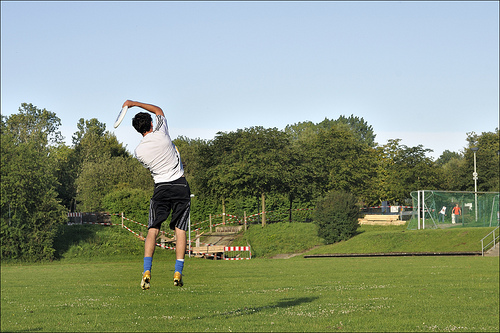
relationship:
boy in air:
[123, 78, 207, 264] [94, 87, 204, 151]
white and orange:
[214, 226, 241, 252] [222, 190, 258, 252]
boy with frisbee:
[122, 99, 195, 292] [105, 91, 139, 128]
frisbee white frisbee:
[114, 106, 129, 128] [105, 91, 139, 128]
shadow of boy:
[224, 280, 345, 325] [122, 99, 195, 292]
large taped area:
[255, 170, 401, 235] [334, 154, 460, 237]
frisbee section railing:
[114, 106, 129, 128] [207, 216, 265, 234]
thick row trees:
[218, 141, 270, 185] [22, 149, 124, 186]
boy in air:
[122, 99, 195, 292] [94, 87, 204, 151]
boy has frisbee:
[122, 99, 195, 292] [105, 91, 139, 128]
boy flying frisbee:
[122, 99, 195, 292] [105, 91, 139, 128]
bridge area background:
[213, 220, 245, 244] [198, 220, 235, 255]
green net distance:
[208, 106, 323, 171] [371, 167, 445, 223]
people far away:
[390, 188, 485, 247] [334, 154, 460, 237]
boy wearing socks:
[122, 99, 195, 292] [137, 259, 184, 275]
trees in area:
[22, 149, 124, 186] [334, 154, 460, 237]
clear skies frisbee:
[172, 28, 249, 61] [105, 91, 139, 128]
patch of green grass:
[280, 287, 348, 306] [251, 254, 359, 287]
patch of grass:
[280, 287, 348, 306] [251, 254, 359, 287]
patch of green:
[280, 287, 348, 306] [208, 106, 323, 171]